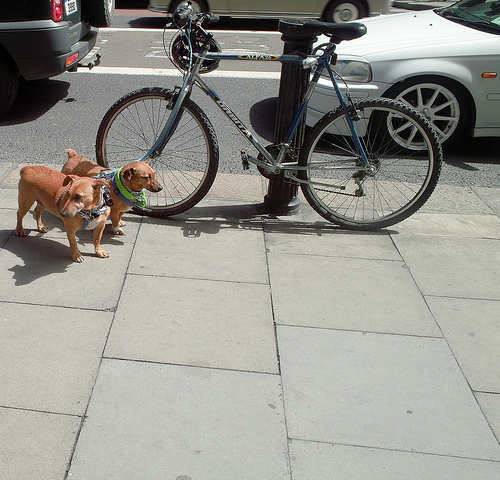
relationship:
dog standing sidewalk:
[14, 166, 109, 264] [0, 162, 499, 479]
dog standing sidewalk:
[63, 148, 162, 236] [0, 162, 499, 479]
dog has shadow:
[14, 166, 109, 264] [1, 228, 98, 286]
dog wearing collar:
[63, 148, 162, 236] [111, 167, 147, 207]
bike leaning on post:
[97, 1, 442, 232] [264, 17, 322, 214]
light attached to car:
[73, 52, 79, 63] [0, 0, 115, 116]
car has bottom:
[0, 0, 115, 116] [1, 20, 98, 113]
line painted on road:
[80, 65, 299, 79] [3, 15, 499, 187]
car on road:
[0, 0, 115, 116] [3, 15, 499, 187]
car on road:
[305, 0, 499, 155] [3, 15, 499, 187]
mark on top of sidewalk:
[405, 408, 412, 415] [0, 162, 499, 479]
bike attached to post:
[97, 1, 442, 232] [264, 17, 322, 214]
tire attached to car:
[373, 76, 470, 156] [305, 0, 499, 155]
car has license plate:
[0, 0, 115, 116] [64, 1, 78, 14]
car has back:
[0, 0, 115, 116] [48, 0, 114, 74]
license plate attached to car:
[64, 1, 78, 14] [0, 0, 115, 116]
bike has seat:
[97, 1, 442, 232] [302, 20, 366, 43]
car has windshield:
[305, 0, 499, 155] [434, 0, 499, 37]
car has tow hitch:
[0, 0, 115, 116] [66, 53, 102, 73]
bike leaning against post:
[97, 1, 442, 232] [264, 17, 322, 214]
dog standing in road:
[14, 166, 109, 264] [3, 15, 499, 187]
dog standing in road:
[63, 148, 162, 236] [3, 15, 499, 187]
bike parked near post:
[97, 1, 442, 232] [264, 17, 322, 214]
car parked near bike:
[305, 0, 499, 155] [97, 1, 442, 232]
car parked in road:
[0, 0, 115, 116] [3, 15, 499, 187]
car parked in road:
[305, 0, 499, 155] [3, 15, 499, 187]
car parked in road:
[147, 1, 393, 29] [3, 15, 499, 187]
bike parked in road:
[97, 1, 442, 232] [3, 15, 499, 187]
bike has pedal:
[97, 1, 442, 232] [239, 148, 281, 175]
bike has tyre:
[97, 1, 442, 232] [94, 86, 220, 219]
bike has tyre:
[97, 1, 442, 232] [299, 97, 443, 232]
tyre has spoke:
[94, 86, 220, 219] [142, 99, 155, 140]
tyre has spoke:
[94, 86, 220, 219] [165, 143, 206, 154]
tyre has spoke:
[94, 86, 220, 219] [160, 167, 167, 207]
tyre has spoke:
[299, 97, 443, 232] [318, 136, 361, 160]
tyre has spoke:
[299, 97, 443, 232] [370, 177, 377, 222]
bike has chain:
[97, 1, 442, 232] [257, 144, 380, 198]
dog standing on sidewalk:
[14, 166, 109, 264] [0, 162, 499, 479]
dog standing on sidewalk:
[63, 148, 162, 236] [0, 162, 499, 479]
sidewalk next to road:
[0, 162, 499, 479] [3, 15, 499, 187]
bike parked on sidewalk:
[97, 1, 442, 232] [0, 162, 499, 479]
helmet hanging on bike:
[172, 31, 221, 74] [97, 1, 442, 232]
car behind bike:
[305, 0, 499, 155] [97, 1, 442, 232]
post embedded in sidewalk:
[264, 17, 322, 214] [0, 162, 499, 479]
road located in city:
[3, 15, 499, 187] [1, 2, 499, 476]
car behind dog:
[0, 0, 115, 116] [14, 166, 109, 264]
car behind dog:
[0, 0, 115, 116] [63, 148, 162, 236]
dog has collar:
[14, 166, 109, 264] [77, 185, 114, 222]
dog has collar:
[63, 148, 162, 236] [111, 167, 147, 207]